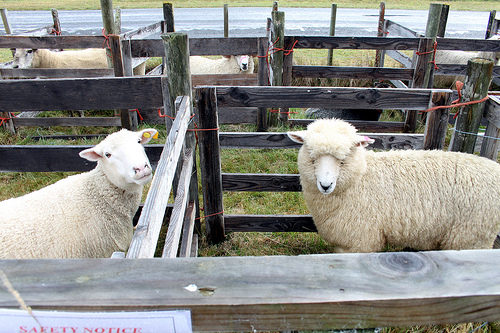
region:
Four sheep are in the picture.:
[1, 30, 491, 272]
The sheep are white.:
[4, 32, 499, 268]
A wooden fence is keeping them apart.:
[157, 62, 241, 295]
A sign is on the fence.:
[0, 293, 212, 330]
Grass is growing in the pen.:
[217, 140, 289, 250]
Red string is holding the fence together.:
[398, 32, 493, 131]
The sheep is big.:
[276, 114, 498, 241]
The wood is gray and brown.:
[246, 258, 398, 323]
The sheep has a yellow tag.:
[131, 120, 172, 149]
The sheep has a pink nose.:
[122, 156, 161, 188]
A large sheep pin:
[7, 4, 499, 322]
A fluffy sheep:
[284, 107, 498, 263]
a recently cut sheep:
[0, 126, 155, 268]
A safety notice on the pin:
[2, 298, 205, 331]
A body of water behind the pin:
[18, 10, 499, 40]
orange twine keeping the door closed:
[425, 65, 485, 122]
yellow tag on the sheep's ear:
[136, 121, 161, 155]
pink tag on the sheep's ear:
[346, 128, 385, 157]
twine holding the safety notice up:
[0, 273, 51, 320]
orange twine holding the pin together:
[176, 101, 238, 246]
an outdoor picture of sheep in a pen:
[0, 0, 499, 332]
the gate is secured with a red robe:
[424, 80, 489, 113]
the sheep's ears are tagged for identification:
[137, 128, 159, 143]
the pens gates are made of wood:
[193, 83, 290, 240]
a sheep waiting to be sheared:
[286, 118, 499, 249]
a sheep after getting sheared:
[1, 127, 158, 259]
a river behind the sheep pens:
[0, 6, 499, 40]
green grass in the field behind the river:
[1, 0, 499, 8]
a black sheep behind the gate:
[304, 78, 396, 122]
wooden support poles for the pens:
[161, 32, 198, 233]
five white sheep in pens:
[10, 18, 489, 270]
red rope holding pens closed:
[180, 116, 227, 148]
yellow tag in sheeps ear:
[130, 112, 167, 152]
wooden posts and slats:
[178, 78, 269, 227]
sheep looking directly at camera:
[68, 116, 170, 228]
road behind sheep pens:
[12, 0, 498, 43]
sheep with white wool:
[298, 107, 495, 232]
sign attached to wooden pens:
[11, 296, 211, 331]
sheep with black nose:
[295, 174, 355, 209]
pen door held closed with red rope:
[413, 92, 498, 123]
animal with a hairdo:
[271, 115, 387, 202]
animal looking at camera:
[75, 115, 156, 200]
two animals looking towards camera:
[53, 68, 428, 238]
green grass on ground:
[242, 189, 297, 230]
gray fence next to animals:
[209, 64, 296, 237]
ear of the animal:
[73, 146, 110, 176]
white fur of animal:
[385, 156, 462, 218]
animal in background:
[0, 29, 89, 85]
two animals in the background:
[11, 38, 253, 110]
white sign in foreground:
[12, 300, 152, 332]